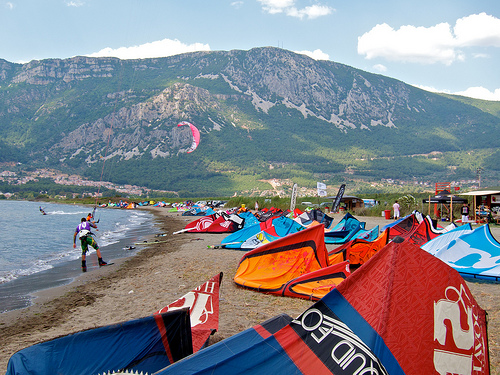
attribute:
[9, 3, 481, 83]
sky — red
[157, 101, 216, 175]
kite — gray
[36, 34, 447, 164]
mountain — brown, green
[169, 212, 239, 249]
kite — white, red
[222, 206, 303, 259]
kite — red, blue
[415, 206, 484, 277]
kite — blue, white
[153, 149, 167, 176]
tree — distant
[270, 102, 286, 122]
tree — distant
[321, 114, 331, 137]
tree — distant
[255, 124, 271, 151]
tree — distant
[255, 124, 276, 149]
tree — distant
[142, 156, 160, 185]
tree — distant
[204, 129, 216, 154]
tree — distant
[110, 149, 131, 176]
tree — distant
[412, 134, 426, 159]
tree — distant